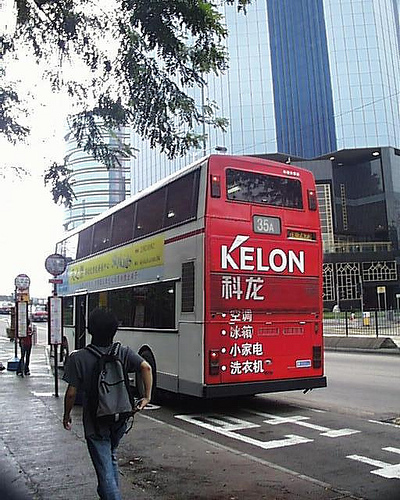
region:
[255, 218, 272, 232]
a number on the bus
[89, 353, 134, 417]
a backpack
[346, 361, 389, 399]
the street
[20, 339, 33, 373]
a person standing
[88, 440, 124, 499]
a person wearing blue jeans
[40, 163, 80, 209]
leaves on the tree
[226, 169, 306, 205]
a windshield on the bus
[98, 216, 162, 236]
windows on the bus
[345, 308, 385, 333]
a fence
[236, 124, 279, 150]
windows on the building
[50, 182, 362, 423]
a large red chinese bus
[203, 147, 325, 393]
the back of a large bus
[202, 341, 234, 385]
the light of a large bus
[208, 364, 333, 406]
the bumper of a large bus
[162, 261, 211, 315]
the vent of a large bus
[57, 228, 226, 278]
the second story of a large bus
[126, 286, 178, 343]
the window of a large bus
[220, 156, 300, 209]
the back window of a large bus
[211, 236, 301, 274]
the brand name of a large bus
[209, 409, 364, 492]
the street signs on the road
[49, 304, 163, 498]
person walking with a backpack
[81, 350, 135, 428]
backpack on the person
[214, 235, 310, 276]
word kelon on the back of the bus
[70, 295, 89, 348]
door on the bus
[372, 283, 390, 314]
sign in front of the building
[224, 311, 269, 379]
foreign language on the back of the bus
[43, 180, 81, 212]
tree limb above the bus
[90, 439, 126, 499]
blue jeans on the person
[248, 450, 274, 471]
white line on the road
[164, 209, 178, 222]
light reflection in the window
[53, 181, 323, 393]
a two level bus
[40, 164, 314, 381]
a white and red bus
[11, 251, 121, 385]
the bus stop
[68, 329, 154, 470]
a man walking on the sidewalk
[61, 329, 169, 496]
a man wearing a grey backpack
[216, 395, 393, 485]
lines painted on the street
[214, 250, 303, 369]
writing on the back of the bus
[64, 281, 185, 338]
windows of the bus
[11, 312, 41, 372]
someone standing at the bus stop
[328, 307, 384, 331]
a black fence behind the bus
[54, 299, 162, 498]
man is walking along street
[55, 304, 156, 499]
man is wearing a grey backpack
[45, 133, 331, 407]
white double decker bus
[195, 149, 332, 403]
bus has red painted back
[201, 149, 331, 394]
white letters on red painted back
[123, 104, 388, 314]
tall mirrored building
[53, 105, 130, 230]
round mirrored building across the street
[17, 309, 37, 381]
woman standing behind sign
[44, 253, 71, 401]
bus stop sign in sidewalk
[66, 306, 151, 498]
man has black hair